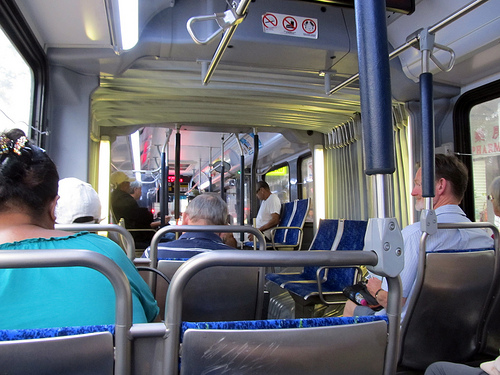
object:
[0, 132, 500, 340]
commuters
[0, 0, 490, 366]
train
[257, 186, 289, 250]
shirt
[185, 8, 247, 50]
handrail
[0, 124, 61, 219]
hair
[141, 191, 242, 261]
man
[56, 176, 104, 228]
hat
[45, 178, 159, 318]
person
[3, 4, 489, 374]
bus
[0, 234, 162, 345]
shirt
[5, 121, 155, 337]
woman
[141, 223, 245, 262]
shirt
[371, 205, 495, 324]
shirt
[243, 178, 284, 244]
man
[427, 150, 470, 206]
hair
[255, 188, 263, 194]
glasses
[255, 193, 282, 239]
shirt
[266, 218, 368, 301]
bench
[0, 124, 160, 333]
lady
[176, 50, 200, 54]
safety handle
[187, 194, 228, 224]
hair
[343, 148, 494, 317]
man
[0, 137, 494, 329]
group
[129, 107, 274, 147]
transit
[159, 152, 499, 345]
two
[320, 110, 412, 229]
drapes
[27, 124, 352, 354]
transit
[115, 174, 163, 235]
two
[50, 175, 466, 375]
transit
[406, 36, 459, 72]
hand rail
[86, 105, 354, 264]
transit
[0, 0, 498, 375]
transit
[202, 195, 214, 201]
balding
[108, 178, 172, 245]
person